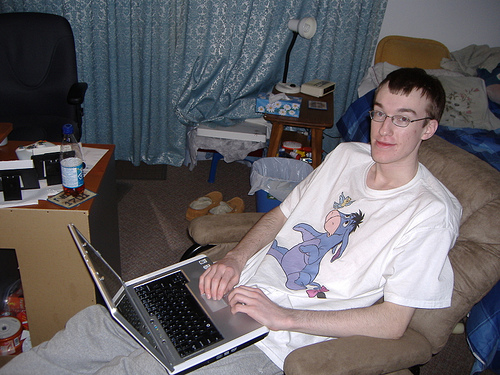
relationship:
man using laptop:
[0, 66, 462, 374] [79, 227, 290, 339]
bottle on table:
[58, 124, 86, 199] [0, 143, 120, 348]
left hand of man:
[223, 283, 280, 332] [0, 66, 462, 374]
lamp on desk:
[272, 15, 317, 97] [263, 90, 333, 169]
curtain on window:
[91, 0, 385, 174] [104, 0, 180, 168]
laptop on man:
[65, 223, 267, 373] [0, 66, 462, 374]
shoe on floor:
[190, 189, 215, 225] [118, 156, 223, 268]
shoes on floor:
[204, 197, 245, 216] [118, 156, 223, 268]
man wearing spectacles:
[0, 66, 462, 374] [366, 107, 431, 129]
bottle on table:
[54, 119, 86, 198] [0, 136, 120, 341]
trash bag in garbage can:
[246, 155, 318, 204] [251, 155, 316, 215]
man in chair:
[0, 66, 462, 374] [178, 134, 498, 374]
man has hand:
[0, 66, 462, 374] [199, 256, 241, 307]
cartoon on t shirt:
[260, 188, 374, 301] [226, 142, 461, 372]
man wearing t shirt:
[220, 38, 460, 368] [226, 142, 461, 372]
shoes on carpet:
[189, 181, 246, 233] [132, 174, 244, 241]